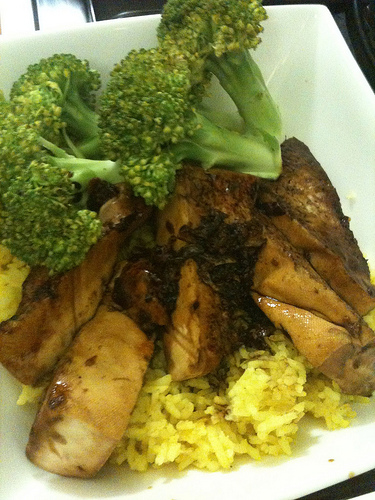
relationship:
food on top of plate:
[3, 1, 374, 484] [2, 1, 374, 498]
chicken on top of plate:
[25, 292, 159, 483] [2, 1, 374, 498]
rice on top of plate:
[259, 441, 282, 457] [2, 1, 374, 498]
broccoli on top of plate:
[99, 1, 292, 208] [2, 1, 374, 498]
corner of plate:
[254, 2, 372, 142] [2, 1, 374, 498]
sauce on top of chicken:
[115, 216, 279, 350] [161, 246, 267, 393]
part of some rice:
[211, 442, 238, 467] [159, 418, 257, 473]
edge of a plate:
[1, 0, 336, 77] [2, 1, 374, 498]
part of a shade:
[116, 467, 156, 496] [0, 369, 190, 500]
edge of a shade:
[40, 478, 158, 499] [0, 369, 190, 500]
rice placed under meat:
[352, 394, 373, 407] [159, 164, 374, 397]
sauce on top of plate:
[115, 216, 279, 350] [2, 1, 374, 498]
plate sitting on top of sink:
[2, 1, 374, 498] [0, 1, 373, 499]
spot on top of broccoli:
[254, 91, 264, 103] [99, 1, 292, 208]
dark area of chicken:
[25, 386, 70, 464] [25, 292, 159, 483]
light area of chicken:
[37, 419, 114, 480] [25, 292, 159, 483]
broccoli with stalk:
[99, 1, 292, 208] [95, 40, 282, 214]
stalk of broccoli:
[95, 40, 282, 214] [99, 1, 292, 208]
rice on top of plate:
[111, 449, 132, 467] [2, 1, 374, 498]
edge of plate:
[1, 0, 336, 77] [2, 1, 374, 498]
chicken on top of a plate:
[161, 246, 267, 393] [2, 1, 374, 498]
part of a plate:
[298, 401, 374, 499] [2, 1, 374, 498]